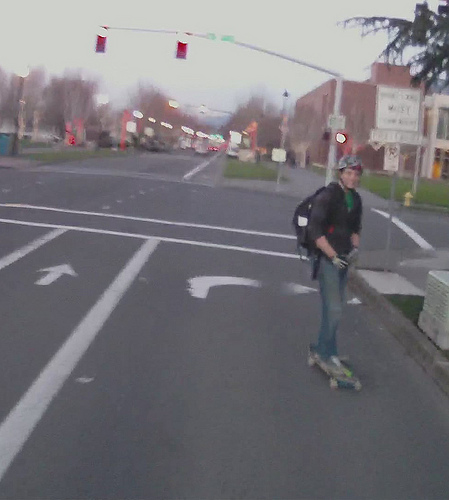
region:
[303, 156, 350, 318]
A skater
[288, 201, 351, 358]
A skater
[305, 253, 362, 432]
A skater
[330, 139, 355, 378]
A skater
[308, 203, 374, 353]
A skater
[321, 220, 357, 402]
A skater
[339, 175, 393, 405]
A skater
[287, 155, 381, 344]
this is a man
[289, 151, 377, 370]
the man is skating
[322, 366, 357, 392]
this is a skate board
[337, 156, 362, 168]
he is wearing a helmet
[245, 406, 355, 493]
the road is tarmacked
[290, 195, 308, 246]
this is a bag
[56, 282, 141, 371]
white strip is on the middle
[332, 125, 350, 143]
light is on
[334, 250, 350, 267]
he is wearing a glove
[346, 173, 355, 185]
the face is white in color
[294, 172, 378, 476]
A man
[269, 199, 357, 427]
A man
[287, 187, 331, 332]
A man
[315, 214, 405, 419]
A man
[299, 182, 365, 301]
A man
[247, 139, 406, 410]
kid skating on the street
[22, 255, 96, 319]
arrow on the street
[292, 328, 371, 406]
skateboard under kid's feet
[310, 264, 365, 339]
jeans on the kid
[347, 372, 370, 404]
wheel on the board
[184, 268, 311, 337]
right turn arrow on street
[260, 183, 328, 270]
backpack on kid's back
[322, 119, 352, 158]
do not walk sign on light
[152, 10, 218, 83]
red light above street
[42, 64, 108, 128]
trees next to the street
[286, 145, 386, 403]
man standing on skateboard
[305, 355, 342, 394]
skateboard wheels on street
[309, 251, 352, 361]
blue jeans on man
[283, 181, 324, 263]
backpack on man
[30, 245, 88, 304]
white arrow on street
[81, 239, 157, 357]
white line in street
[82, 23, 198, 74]
two traffic lights on pole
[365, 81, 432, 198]
white signs on pole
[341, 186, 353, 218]
top of green shirt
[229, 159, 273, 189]
green grass on ground